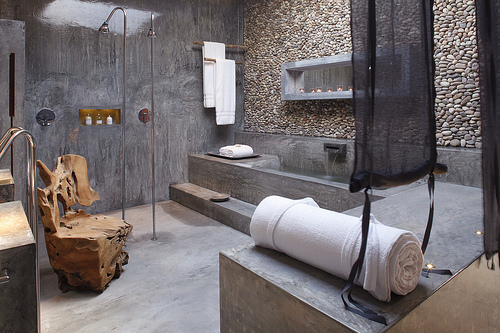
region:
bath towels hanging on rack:
[190, 32, 251, 132]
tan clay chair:
[35, 149, 131, 299]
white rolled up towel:
[247, 183, 429, 300]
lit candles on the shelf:
[297, 80, 372, 96]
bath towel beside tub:
[218, 141, 259, 163]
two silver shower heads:
[86, 8, 160, 64]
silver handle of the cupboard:
[3, 260, 14, 289]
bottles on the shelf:
[84, 108, 121, 130]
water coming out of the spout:
[317, 138, 348, 173]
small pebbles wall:
[440, 23, 473, 65]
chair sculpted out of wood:
[33, 149, 131, 292]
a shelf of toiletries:
[76, 103, 126, 128]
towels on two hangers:
[203, 41, 235, 125]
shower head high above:
[98, 22, 111, 34]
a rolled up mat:
[250, 193, 423, 302]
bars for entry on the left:
[0, 125, 44, 331]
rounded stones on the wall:
[238, 0, 355, 136]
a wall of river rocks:
[437, 3, 476, 145]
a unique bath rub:
[245, 157, 412, 197]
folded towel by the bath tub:
[219, 144, 251, 156]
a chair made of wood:
[41, 145, 118, 310]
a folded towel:
[208, 142, 265, 176]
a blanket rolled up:
[237, 200, 424, 295]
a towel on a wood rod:
[192, 51, 249, 118]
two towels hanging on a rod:
[195, 36, 241, 119]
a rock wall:
[242, 8, 317, 73]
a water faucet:
[315, 133, 345, 166]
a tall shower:
[133, 6, 158, 256]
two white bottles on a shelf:
[77, 96, 118, 133]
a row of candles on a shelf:
[290, 85, 351, 99]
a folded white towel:
[215, 139, 256, 161]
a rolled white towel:
[243, 188, 429, 306]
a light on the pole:
[96, 17, 114, 37]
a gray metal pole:
[103, 5, 138, 225]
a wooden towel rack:
[190, 38, 255, 53]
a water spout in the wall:
[319, 136, 350, 156]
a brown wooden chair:
[27, 140, 136, 292]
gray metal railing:
[1, 123, 46, 331]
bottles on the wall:
[80, 102, 122, 127]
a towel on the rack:
[211, 54, 241, 131]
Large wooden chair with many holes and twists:
[32, 150, 136, 288]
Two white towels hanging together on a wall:
[194, 39, 243, 124]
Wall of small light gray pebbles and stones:
[431, 4, 481, 149]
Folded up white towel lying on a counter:
[238, 189, 432, 296]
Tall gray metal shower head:
[90, 5, 178, 243]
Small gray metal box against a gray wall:
[318, 136, 350, 159]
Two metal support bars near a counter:
[0, 114, 49, 287]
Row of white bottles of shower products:
[72, 102, 125, 129]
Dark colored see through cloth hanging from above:
[342, 0, 436, 194]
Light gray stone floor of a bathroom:
[141, 241, 208, 303]